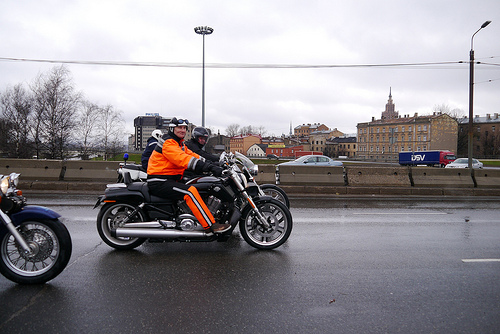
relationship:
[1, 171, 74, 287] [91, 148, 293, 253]
front end of a motorcycle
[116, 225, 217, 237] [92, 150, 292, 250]
pipe on bike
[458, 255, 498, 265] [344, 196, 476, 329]
line on road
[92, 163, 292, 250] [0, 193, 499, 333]
bike on road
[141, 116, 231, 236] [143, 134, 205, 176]
man wearing jacket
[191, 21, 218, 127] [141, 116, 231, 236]
pole standing behind man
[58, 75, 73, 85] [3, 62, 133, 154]
branch growing on tree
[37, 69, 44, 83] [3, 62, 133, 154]
branch growing on tree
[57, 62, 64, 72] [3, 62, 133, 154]
branch growing on tree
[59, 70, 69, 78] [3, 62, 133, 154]
branch growing on tree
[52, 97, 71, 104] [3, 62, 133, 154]
branch growing on tree